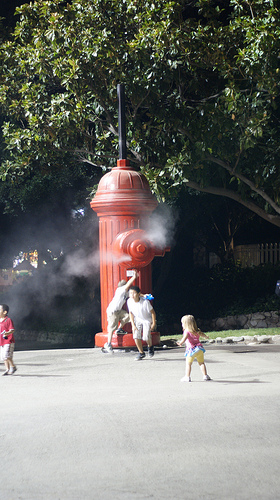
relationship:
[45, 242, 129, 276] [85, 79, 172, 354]
steam coming off fire hydrant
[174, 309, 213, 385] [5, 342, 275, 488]
kid on road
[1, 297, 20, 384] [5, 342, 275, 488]
kid on road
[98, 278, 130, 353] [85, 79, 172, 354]
kid crawling on fire hydrant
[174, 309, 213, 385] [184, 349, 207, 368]
kid wearing shorts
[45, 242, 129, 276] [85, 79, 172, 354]
steam coming out of fire hydrant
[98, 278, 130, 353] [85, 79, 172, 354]
kid playing with fire hydrant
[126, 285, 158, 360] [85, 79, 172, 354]
boys playing with fire hydrant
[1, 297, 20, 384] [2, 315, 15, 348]
kid has shirt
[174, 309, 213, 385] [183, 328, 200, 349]
kid has shirt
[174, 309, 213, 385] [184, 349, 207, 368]
kid has shorts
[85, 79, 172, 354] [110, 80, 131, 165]
fire hydrant has pole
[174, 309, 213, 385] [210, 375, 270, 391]
kid has shadow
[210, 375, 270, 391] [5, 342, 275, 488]
shadow on road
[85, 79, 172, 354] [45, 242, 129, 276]
fire hydrant has steam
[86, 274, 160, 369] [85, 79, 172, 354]
boys are playing in front fire hydrant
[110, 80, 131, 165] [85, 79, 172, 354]
pole on top of fire hydrant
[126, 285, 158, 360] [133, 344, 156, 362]
boys has sneakers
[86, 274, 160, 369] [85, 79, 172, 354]
boys are playing with fire hydrant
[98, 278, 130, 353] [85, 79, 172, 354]
kid climbing on fire hydrant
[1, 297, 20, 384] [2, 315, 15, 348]
kid wearing shirt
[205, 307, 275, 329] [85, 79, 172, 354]
border next to fire hydrant